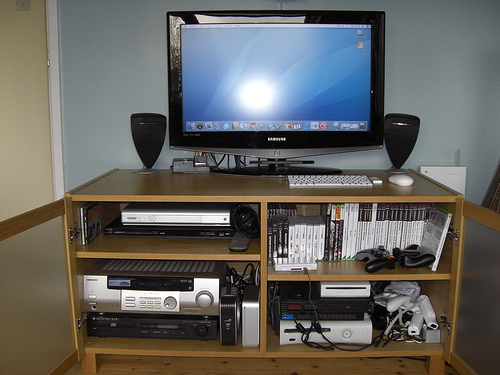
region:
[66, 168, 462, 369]
wooden entertainment center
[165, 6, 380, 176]
large flatscreen tv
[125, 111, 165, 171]
black speaker next to tv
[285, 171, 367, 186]
white keyboard in front of tv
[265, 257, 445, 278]
wooden shelf with video games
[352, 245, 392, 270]
black controller on shelf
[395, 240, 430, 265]
black controller on shelf next to controller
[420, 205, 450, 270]
white video game next to black controller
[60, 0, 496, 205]
blue painted wall behind entertainment center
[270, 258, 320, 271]
white wii controller on shelf across from black controller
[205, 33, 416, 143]
screen is on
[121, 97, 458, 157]
two speakers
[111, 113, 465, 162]
speakers on each side of screen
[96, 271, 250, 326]
stereo on the shelf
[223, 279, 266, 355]
router on the shelf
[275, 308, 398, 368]
game console on the shelf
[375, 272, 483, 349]
remote controls on the shelf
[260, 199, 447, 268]
games for game console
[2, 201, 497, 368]
stereo stand doors are open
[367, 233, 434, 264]
two black game controllers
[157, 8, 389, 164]
a black flat screen TV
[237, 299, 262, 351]
an Apple Mac Mini computer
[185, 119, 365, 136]
Mac OS X dock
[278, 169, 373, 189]
Apple wireless computer keyboard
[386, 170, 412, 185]
white Apple Magic Mouse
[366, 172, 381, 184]
white Apple remote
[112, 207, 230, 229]
a silver DVD player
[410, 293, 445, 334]
a Wii game controller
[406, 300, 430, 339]
a Wii game controller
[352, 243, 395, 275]
an Xbox game controller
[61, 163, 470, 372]
A TV stand.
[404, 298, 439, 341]
Two Wii controllers.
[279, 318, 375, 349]
A white XBOX 360.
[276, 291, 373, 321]
A black Playstation.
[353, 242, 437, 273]
Two black XBOX controllers.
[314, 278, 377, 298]
A white Wii game system.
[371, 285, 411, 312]
A white xbox controller.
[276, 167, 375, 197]
A small computer keyboard.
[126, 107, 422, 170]
Two black speakers.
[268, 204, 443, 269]
A row of video games.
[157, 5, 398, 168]
tv on top of entertainment system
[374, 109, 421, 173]
speaker on side of tv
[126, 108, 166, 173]
speaker on side of tv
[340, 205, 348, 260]
dvd on top shelf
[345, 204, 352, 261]
dvd on top shelf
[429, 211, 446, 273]
dvd on top shelf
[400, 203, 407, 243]
dvd on top shelf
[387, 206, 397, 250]
dvd on top shelf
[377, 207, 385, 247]
dvd on top shelf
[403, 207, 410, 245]
dvd on top shelf